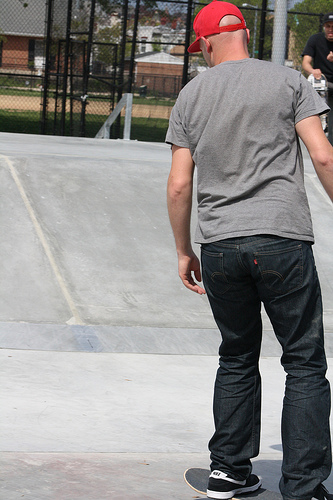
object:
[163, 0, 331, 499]
man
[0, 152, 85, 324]
line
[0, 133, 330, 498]
concrete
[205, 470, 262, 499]
sneaker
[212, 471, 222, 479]
logo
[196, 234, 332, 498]
pants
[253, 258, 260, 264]
tag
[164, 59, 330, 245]
shirt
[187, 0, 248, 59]
hat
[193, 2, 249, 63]
head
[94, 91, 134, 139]
railing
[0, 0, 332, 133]
fence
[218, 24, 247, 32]
fastener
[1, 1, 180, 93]
house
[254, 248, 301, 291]
pocket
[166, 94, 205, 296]
arm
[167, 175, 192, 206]
elbow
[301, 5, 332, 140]
man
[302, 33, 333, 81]
shirt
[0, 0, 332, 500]
skate park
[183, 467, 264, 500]
skateboard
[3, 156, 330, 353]
ramp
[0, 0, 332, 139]
background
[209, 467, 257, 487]
tape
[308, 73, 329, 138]
skateboard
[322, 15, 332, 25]
hat